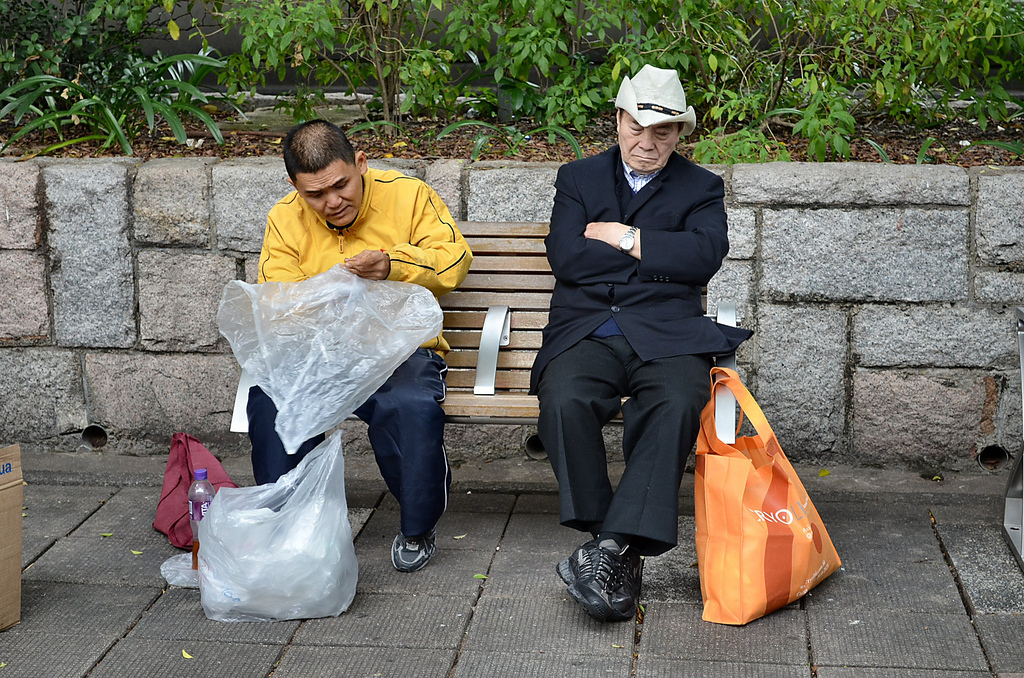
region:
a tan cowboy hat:
[609, 54, 702, 135]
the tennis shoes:
[388, 528, 645, 626]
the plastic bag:
[157, 257, 449, 621]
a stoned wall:
[5, 145, 1023, 493]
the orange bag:
[692, 361, 844, 630]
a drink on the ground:
[183, 461, 219, 578]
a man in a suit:
[533, 53, 733, 626]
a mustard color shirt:
[252, 171, 478, 353]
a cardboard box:
[2, 430, 31, 634]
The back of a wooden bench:
[485, 235, 539, 302]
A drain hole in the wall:
[84, 426, 104, 446]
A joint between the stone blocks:
[38, 198, 46, 250]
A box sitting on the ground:
[0, 489, 19, 625]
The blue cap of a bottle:
[195, 468, 206, 478]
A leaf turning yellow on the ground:
[180, 651, 191, 659]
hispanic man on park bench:
[254, 134, 476, 505]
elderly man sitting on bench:
[549, 70, 750, 582]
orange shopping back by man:
[707, 338, 862, 661]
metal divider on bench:
[467, 308, 494, 385]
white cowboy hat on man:
[579, 55, 709, 129]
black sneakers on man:
[577, 538, 655, 618]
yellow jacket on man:
[239, 178, 487, 344]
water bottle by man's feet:
[182, 472, 220, 559]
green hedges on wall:
[11, 3, 1004, 158]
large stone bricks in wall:
[8, 178, 955, 460]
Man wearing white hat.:
[610, 54, 713, 132]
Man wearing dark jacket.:
[537, 142, 731, 377]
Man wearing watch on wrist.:
[612, 221, 638, 273]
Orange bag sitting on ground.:
[686, 377, 833, 660]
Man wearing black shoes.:
[558, 546, 677, 648]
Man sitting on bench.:
[508, 160, 730, 614]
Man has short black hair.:
[272, 108, 380, 169]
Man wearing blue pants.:
[236, 334, 461, 541]